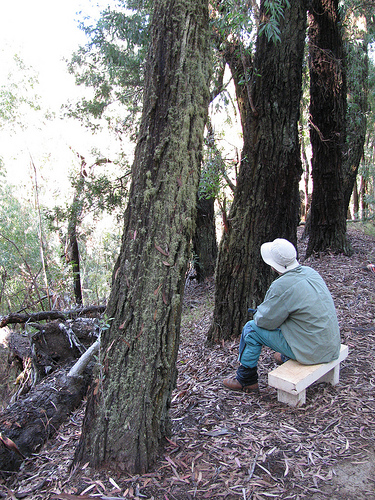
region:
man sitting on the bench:
[225, 220, 357, 432]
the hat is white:
[255, 229, 300, 276]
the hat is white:
[243, 220, 312, 296]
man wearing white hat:
[261, 236, 302, 277]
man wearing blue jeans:
[229, 321, 282, 370]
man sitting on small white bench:
[264, 333, 357, 414]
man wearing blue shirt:
[255, 264, 347, 365]